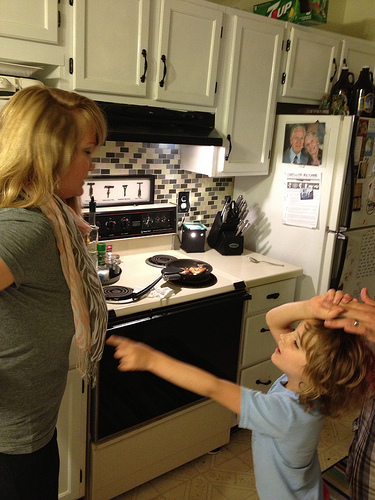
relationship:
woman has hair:
[1, 85, 109, 500] [1, 85, 108, 212]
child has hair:
[104, 319, 371, 500] [298, 316, 374, 421]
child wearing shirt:
[104, 319, 371, 500] [233, 372, 331, 499]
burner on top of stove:
[103, 283, 134, 301] [77, 231, 245, 323]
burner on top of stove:
[149, 252, 176, 266] [77, 231, 245, 323]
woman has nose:
[1, 85, 109, 500] [88, 155, 96, 171]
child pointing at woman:
[104, 319, 371, 500] [1, 85, 109, 500]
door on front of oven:
[90, 287, 252, 444] [74, 202, 252, 499]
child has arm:
[104, 319, 371, 500] [146, 346, 284, 439]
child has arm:
[104, 319, 371, 500] [264, 286, 358, 352]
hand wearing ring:
[321, 287, 374, 346] [350, 316, 361, 328]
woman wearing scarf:
[1, 85, 109, 500] [18, 184, 108, 391]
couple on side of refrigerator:
[282, 127, 322, 167] [231, 111, 373, 332]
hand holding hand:
[321, 287, 374, 346] [309, 286, 356, 320]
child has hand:
[104, 319, 371, 500] [309, 286, 356, 320]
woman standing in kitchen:
[1, 85, 109, 500] [1, 0, 374, 497]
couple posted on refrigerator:
[282, 127, 322, 167] [231, 111, 373, 332]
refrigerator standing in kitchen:
[231, 111, 373, 332] [1, 0, 374, 497]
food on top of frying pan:
[181, 267, 205, 275] [163, 258, 213, 287]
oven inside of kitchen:
[74, 202, 252, 499] [1, 0, 374, 497]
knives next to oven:
[221, 191, 249, 239] [74, 202, 252, 499]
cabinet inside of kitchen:
[180, 14, 285, 178] [1, 0, 374, 497]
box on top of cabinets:
[250, 0, 331, 31] [1, 0, 374, 179]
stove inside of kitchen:
[77, 231, 245, 323] [1, 0, 374, 497]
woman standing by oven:
[1, 85, 109, 500] [74, 202, 252, 499]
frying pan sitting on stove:
[163, 258, 213, 287] [77, 231, 245, 323]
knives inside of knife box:
[221, 191, 249, 239] [207, 211, 245, 256]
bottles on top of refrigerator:
[327, 64, 374, 121] [231, 111, 373, 332]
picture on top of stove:
[80, 173, 158, 205] [77, 231, 245, 323]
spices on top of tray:
[94, 239, 115, 274] [96, 258, 123, 285]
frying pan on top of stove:
[163, 258, 213, 287] [77, 231, 245, 323]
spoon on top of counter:
[247, 257, 285, 267] [174, 241, 303, 286]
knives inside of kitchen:
[221, 191, 249, 239] [1, 0, 374, 497]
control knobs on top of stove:
[101, 213, 130, 231] [77, 231, 245, 323]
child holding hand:
[104, 319, 371, 500] [321, 287, 374, 346]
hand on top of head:
[321, 287, 374, 346] [271, 313, 374, 420]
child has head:
[104, 319, 371, 500] [271, 313, 374, 420]